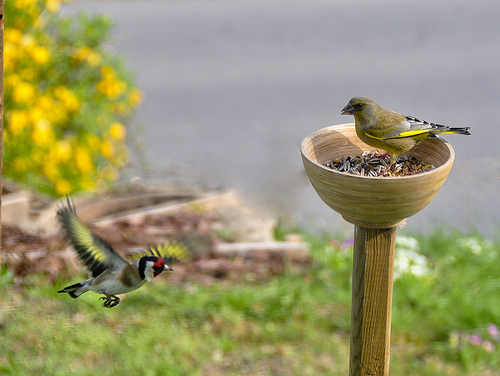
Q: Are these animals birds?
A: Yes, all the animals are birds.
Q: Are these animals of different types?
A: No, all the animals are birds.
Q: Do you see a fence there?
A: No, there are no fences.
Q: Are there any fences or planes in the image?
A: No, there are no fences or planes.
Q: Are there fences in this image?
A: No, there are no fences.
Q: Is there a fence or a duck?
A: No, there are no fences or ducks.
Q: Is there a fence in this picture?
A: No, there are no fences.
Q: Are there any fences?
A: No, there are no fences.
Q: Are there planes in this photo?
A: No, there are no planes.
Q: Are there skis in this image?
A: No, there are no skis.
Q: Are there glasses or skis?
A: No, there are no skis or glasses.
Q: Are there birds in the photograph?
A: Yes, there is a bird.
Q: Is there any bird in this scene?
A: Yes, there is a bird.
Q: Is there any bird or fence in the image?
A: Yes, there is a bird.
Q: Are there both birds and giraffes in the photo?
A: No, there is a bird but no giraffes.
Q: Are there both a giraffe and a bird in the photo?
A: No, there is a bird but no giraffes.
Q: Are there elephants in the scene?
A: No, there are no elephants.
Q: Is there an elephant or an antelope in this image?
A: No, there are no elephants or antelopes.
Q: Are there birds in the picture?
A: Yes, there is a bird.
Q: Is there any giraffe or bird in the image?
A: Yes, there is a bird.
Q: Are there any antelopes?
A: No, there are no antelopes.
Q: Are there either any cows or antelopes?
A: No, there are no antelopes or cows.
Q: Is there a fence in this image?
A: No, there are no fences.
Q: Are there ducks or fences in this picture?
A: No, there are no fences or ducks.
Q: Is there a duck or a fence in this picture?
A: No, there are no fences or ducks.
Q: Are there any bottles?
A: No, there are no bottles.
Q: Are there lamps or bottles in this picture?
A: No, there are no bottles or lamps.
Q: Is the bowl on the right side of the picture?
A: Yes, the bowl is on the right of the image.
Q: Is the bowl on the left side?
A: No, the bowl is on the right of the image.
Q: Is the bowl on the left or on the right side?
A: The bowl is on the right of the image.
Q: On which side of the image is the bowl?
A: The bowl is on the right of the image.